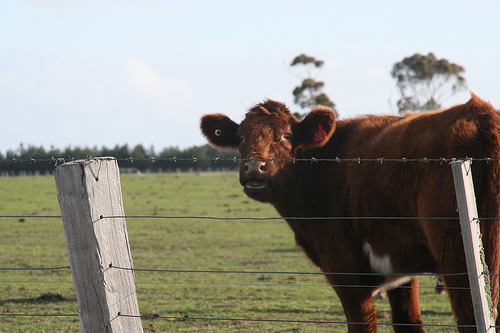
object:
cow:
[199, 89, 499, 332]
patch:
[362, 240, 395, 276]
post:
[54, 156, 144, 332]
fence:
[0, 154, 499, 332]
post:
[447, 158, 496, 332]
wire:
[1, 154, 500, 164]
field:
[0, 171, 459, 332]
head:
[199, 98, 336, 203]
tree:
[283, 53, 339, 121]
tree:
[390, 52, 466, 116]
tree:
[130, 142, 148, 174]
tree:
[116, 142, 132, 174]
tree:
[157, 145, 181, 173]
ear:
[199, 112, 244, 151]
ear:
[297, 104, 337, 149]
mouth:
[244, 176, 268, 189]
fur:
[200, 91, 499, 332]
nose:
[243, 160, 268, 176]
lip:
[244, 176, 266, 183]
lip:
[244, 181, 267, 190]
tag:
[313, 123, 328, 142]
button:
[214, 128, 222, 136]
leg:
[385, 276, 425, 332]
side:
[258, 89, 498, 332]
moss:
[475, 219, 495, 317]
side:
[460, 158, 496, 332]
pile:
[37, 291, 66, 301]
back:
[296, 89, 499, 141]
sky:
[0, 0, 500, 144]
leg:
[296, 230, 377, 332]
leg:
[410, 190, 498, 331]